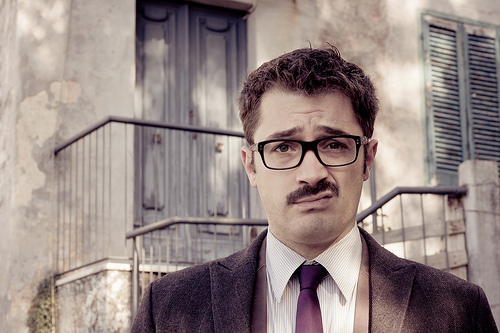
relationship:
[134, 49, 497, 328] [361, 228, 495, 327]
man has shoulder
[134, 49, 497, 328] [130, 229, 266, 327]
man has shoulder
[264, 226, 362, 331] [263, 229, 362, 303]
shirt has collar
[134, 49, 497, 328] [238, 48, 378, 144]
man has hair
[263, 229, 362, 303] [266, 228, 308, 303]
collar has point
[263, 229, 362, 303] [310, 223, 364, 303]
collar has point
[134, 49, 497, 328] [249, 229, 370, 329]
man wearing suit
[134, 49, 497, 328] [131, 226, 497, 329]
man wearing coat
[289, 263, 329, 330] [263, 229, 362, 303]
tie in middle of collar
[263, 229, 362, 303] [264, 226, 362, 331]
collar part of shirt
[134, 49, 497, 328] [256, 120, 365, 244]
man has face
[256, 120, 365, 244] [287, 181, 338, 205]
face has mustache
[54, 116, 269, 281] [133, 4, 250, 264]
railing in front of door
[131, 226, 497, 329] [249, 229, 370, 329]
coat on top of suit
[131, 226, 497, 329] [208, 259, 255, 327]
coat has lapel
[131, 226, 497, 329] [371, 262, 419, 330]
coat has lapel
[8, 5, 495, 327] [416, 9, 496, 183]
building has window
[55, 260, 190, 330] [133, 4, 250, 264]
platform in front of door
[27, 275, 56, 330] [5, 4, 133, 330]
vegetation on top of wall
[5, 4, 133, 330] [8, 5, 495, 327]
wall part of building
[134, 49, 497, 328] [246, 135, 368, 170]
man iw wearing spectacle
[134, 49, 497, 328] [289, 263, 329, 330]
man wearing tie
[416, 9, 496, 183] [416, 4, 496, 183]
window are on top of window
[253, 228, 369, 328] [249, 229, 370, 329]
jacket part of suit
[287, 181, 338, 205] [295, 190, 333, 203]
mustache on top of lip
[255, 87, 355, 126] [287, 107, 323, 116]
forehead has crease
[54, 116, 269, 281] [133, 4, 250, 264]
railing surrounding door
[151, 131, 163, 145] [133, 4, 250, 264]
handle on front of door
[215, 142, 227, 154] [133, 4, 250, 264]
handle on front of door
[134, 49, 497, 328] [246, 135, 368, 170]
man wearing spectacle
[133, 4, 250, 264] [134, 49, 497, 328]
door behind man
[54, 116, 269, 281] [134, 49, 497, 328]
railing behind man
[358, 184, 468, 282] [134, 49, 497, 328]
railing behind man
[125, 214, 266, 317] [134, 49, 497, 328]
railing behind man